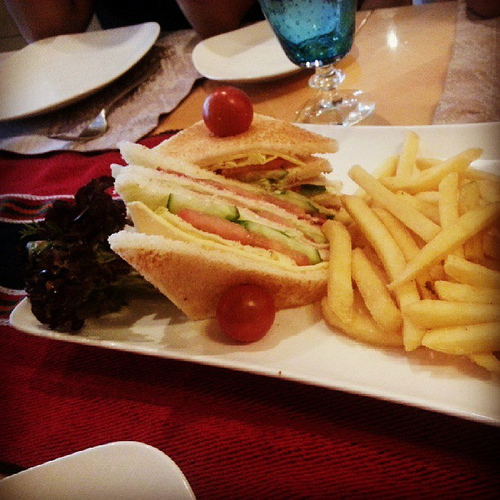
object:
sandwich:
[110, 84, 339, 346]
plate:
[7, 119, 499, 427]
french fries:
[319, 129, 499, 375]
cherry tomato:
[203, 84, 254, 138]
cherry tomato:
[215, 281, 274, 345]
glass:
[261, 0, 375, 127]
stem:
[308, 62, 346, 104]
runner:
[1, 128, 498, 496]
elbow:
[189, 15, 240, 39]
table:
[0, 0, 500, 500]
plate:
[1, 439, 201, 500]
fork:
[46, 73, 154, 142]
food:
[26, 85, 499, 373]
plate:
[192, 16, 312, 83]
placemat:
[1, 27, 205, 158]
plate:
[1, 21, 160, 126]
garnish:
[21, 174, 161, 334]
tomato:
[183, 206, 307, 266]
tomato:
[221, 156, 297, 176]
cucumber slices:
[164, 192, 321, 265]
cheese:
[127, 199, 329, 271]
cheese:
[204, 150, 306, 170]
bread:
[105, 228, 328, 320]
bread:
[148, 106, 339, 161]